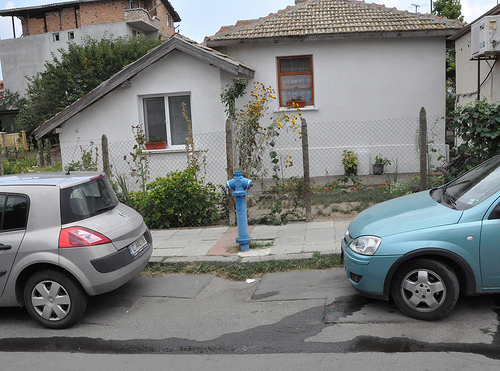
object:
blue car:
[338, 156, 499, 320]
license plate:
[127, 235, 148, 258]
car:
[1, 169, 153, 327]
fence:
[154, 132, 212, 202]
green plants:
[317, 209, 333, 219]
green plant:
[341, 148, 357, 172]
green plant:
[375, 153, 391, 166]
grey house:
[34, 29, 254, 222]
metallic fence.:
[116, 139, 135, 199]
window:
[278, 54, 314, 105]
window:
[168, 95, 191, 144]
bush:
[145, 169, 215, 229]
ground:
[165, 229, 200, 258]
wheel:
[390, 257, 460, 321]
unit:
[470, 18, 498, 60]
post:
[418, 105, 428, 191]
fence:
[309, 121, 365, 208]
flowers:
[301, 116, 303, 120]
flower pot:
[286, 101, 305, 108]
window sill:
[274, 108, 318, 113]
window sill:
[139, 146, 194, 154]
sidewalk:
[145, 212, 340, 258]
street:
[0, 265, 498, 370]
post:
[301, 118, 311, 219]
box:
[145, 142, 166, 150]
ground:
[286, 221, 325, 253]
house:
[199, 2, 466, 182]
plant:
[455, 98, 499, 170]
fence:
[445, 66, 498, 159]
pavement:
[121, 276, 335, 368]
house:
[1, 0, 181, 42]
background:
[0, 1, 495, 132]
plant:
[263, 177, 305, 223]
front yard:
[113, 158, 444, 229]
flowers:
[279, 110, 281, 112]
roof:
[34, 35, 172, 140]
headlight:
[348, 235, 382, 254]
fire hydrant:
[225, 169, 253, 250]